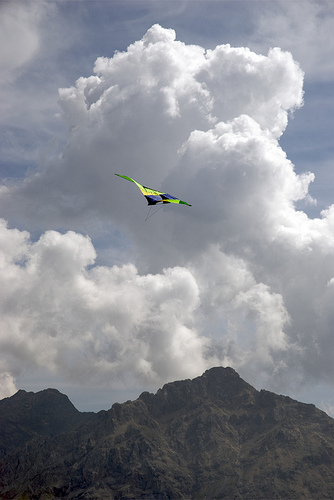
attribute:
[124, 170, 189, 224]
parasail — green, dark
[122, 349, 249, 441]
moutain — brown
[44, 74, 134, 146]
sky — white, cloud, blue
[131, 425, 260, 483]
area — low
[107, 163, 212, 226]
kite — blue, yellow, big, wing, connected, color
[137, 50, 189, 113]
cloud — fluffy, white, big, dark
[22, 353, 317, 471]
mountain — background, large, peak, range, brown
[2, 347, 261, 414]
peak — shorter